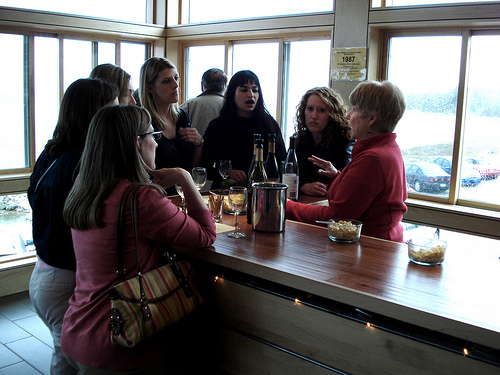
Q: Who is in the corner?
A: A man.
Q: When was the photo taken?
A: Day time.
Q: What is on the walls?
A: Windows.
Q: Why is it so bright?
A: Sunny.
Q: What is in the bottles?
A: Wine.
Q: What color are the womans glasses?
A: Black.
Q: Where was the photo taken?
A: In building.